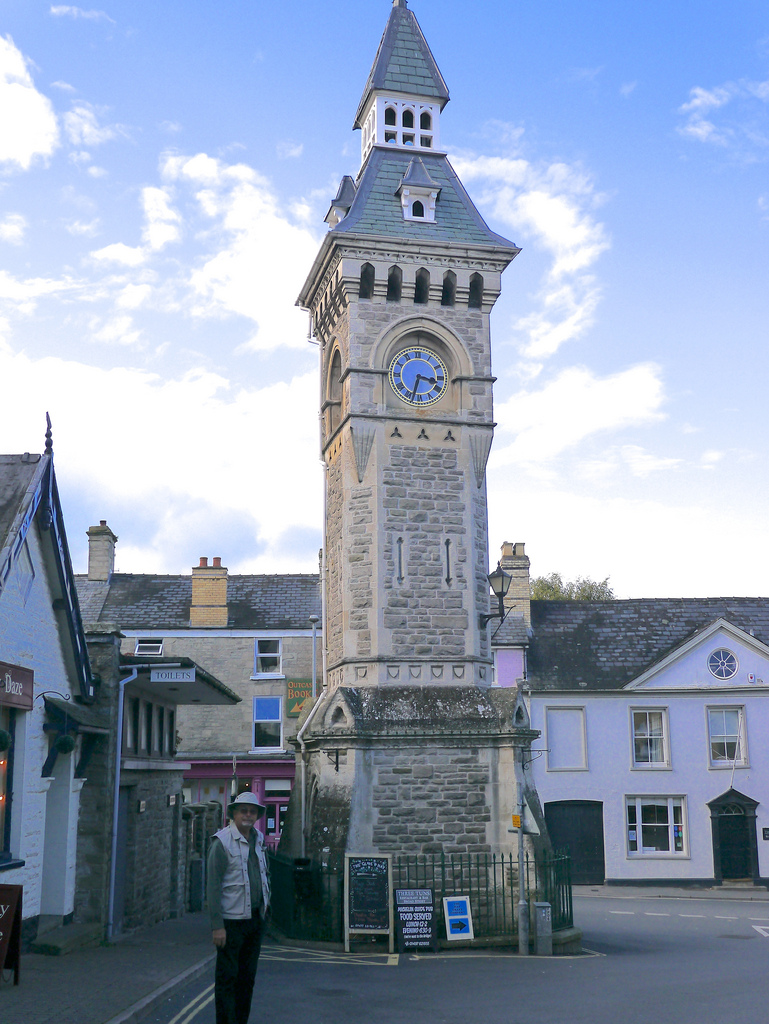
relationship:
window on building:
[253, 697, 281, 750] [80, 519, 454, 918]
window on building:
[255, 639, 276, 675] [77, 519, 512, 970]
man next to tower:
[196, 793, 272, 1020] [275, 3, 524, 912]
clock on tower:
[392, 342, 445, 401] [263, 0, 559, 946]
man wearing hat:
[196, 793, 272, 1020] [227, 787, 265, 812]